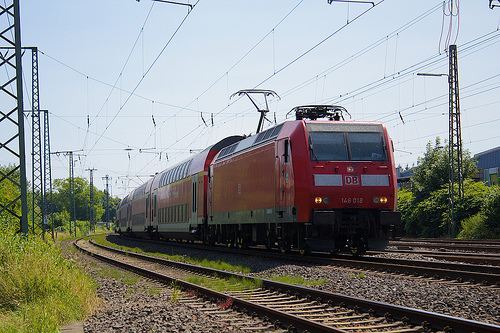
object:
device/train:
[228, 83, 278, 131]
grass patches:
[200, 273, 257, 287]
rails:
[97, 239, 276, 330]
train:
[104, 97, 406, 263]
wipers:
[306, 135, 319, 163]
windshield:
[306, 123, 384, 163]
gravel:
[321, 272, 385, 302]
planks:
[234, 284, 271, 296]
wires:
[351, 3, 406, 52]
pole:
[438, 38, 464, 174]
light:
[415, 68, 455, 81]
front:
[286, 114, 404, 241]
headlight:
[313, 194, 330, 204]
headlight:
[373, 192, 390, 206]